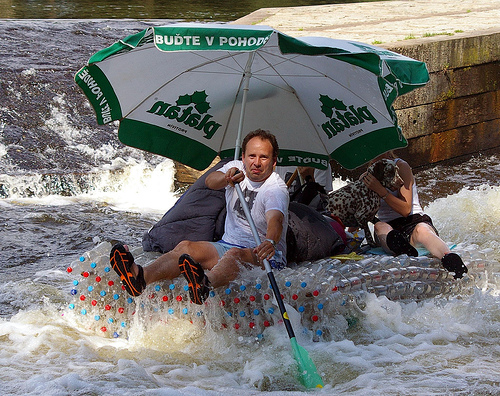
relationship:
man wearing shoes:
[212, 134, 294, 267] [96, 236, 213, 311]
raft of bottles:
[62, 227, 456, 337] [357, 277, 400, 294]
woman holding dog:
[376, 157, 457, 263] [327, 165, 406, 223]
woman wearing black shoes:
[376, 157, 457, 263] [388, 235, 480, 285]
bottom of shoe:
[107, 250, 143, 297] [180, 252, 215, 302]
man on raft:
[212, 134, 294, 267] [62, 227, 456, 337]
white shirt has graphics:
[220, 187, 268, 247] [236, 191, 255, 213]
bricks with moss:
[372, 14, 475, 83] [424, 66, 498, 123]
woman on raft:
[376, 157, 457, 263] [62, 227, 456, 337]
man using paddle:
[212, 134, 294, 267] [266, 291, 334, 386]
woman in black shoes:
[376, 157, 457, 263] [388, 235, 480, 285]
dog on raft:
[327, 165, 406, 223] [62, 227, 456, 337]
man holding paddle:
[212, 134, 294, 267] [266, 291, 334, 386]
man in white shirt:
[212, 134, 294, 267] [220, 187, 268, 247]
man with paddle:
[212, 134, 294, 267] [266, 291, 334, 386]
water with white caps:
[28, 138, 117, 234] [387, 321, 473, 378]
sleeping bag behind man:
[163, 186, 201, 243] [212, 134, 294, 267]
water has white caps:
[28, 138, 117, 234] [387, 321, 473, 378]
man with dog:
[212, 134, 294, 267] [327, 165, 406, 223]